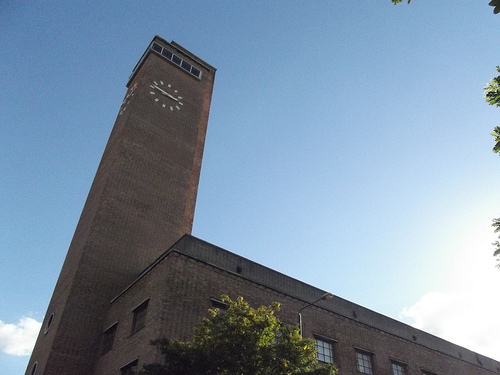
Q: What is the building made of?
A: Brick.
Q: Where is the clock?
A: Side of tower.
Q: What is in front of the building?
A: Tree.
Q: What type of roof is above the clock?
A: Flat.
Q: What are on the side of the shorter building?
A: Windows.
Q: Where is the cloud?
A: Bottom left in sky.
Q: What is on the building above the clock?
A: Windows.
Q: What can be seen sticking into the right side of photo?
A: Leaves.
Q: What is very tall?
A: The clock tower.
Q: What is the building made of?
A: Bricks.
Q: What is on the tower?
A: A large clock.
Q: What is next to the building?
A: A green tree.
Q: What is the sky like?
A: Clear and blue.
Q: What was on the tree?
A: Green leaves.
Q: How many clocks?
A: 1.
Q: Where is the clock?
A: On the building.